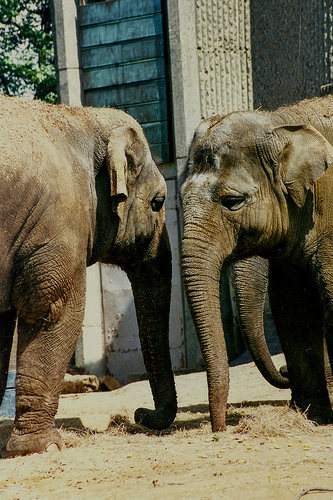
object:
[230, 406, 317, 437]
hay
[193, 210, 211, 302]
skin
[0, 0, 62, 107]
tree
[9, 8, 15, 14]
leaves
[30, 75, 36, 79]
leaves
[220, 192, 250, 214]
eye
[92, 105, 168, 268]
head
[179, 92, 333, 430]
elephant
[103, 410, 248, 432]
shadow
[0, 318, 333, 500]
ground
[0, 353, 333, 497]
dirt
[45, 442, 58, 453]
toe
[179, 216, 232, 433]
trunk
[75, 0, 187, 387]
door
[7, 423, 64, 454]
foot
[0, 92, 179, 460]
elephant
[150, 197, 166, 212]
eye